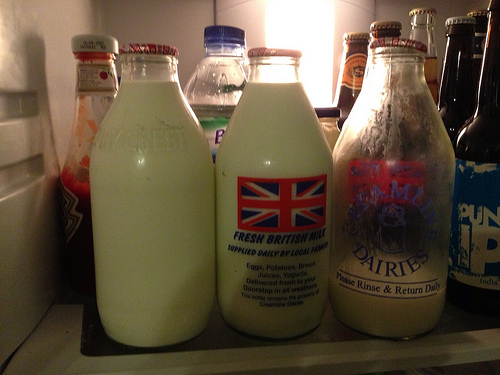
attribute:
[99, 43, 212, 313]
milk — green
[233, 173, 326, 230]
flag — jack flag, blue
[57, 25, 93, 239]
ketchup — red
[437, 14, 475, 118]
bottle — beer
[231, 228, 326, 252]
text — blue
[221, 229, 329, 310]
logo — blue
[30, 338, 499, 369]
shelf — white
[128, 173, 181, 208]
liquid — white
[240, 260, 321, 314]
letters — black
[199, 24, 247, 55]
cap — blue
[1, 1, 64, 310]
refrigerator — white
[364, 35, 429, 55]
lid — on